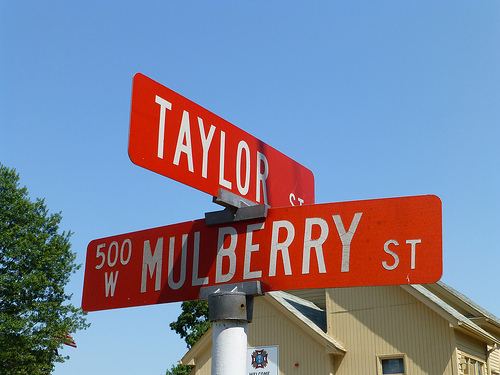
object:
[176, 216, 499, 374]
building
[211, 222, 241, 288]
letter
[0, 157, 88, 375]
tree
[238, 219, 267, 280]
letter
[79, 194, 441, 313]
sign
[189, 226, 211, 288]
letter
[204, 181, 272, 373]
pole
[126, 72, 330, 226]
sign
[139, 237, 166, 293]
letter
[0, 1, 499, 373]
sky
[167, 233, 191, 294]
letter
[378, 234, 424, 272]
abbreviation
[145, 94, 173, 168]
letter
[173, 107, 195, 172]
letter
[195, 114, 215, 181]
letter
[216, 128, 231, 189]
letter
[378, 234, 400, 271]
letter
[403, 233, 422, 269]
letter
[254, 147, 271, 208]
letter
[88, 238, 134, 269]
number 500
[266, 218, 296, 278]
letter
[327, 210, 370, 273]
letter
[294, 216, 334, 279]
sign